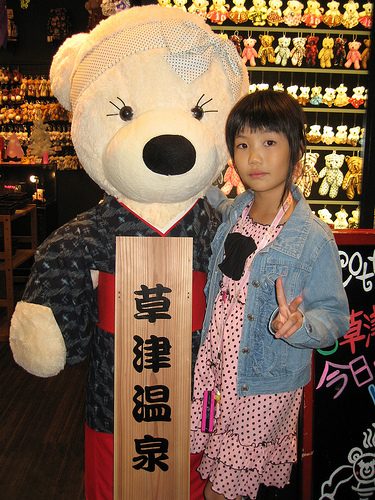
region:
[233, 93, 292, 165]
girl has brown hair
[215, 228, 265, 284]
girl has black bow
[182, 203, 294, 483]
girl has pink dress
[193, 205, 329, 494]
black dots on dress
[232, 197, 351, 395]
girl has blue jacket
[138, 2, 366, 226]
toy bears behind girl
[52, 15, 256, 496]
large bear next to girl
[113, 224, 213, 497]
black and brown sign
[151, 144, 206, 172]
bear has black nose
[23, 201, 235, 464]
black and grey shirt on bear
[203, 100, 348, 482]
a little girl that is posing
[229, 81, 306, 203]
the head of a little girl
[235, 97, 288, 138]
the bangs of a little girl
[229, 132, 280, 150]
the eyes of a little girl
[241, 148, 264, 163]
the nose of a little girl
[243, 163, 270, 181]
the mouth of a little girl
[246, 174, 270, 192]
the chin of a little girl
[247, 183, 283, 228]
the neck of a little girl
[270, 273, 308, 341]
the hand of a little girl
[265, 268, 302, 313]
the fingers of a little girl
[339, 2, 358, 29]
teddy bear on shelf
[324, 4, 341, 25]
teddy bear on shelf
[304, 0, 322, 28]
teddy bear on shelf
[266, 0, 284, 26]
teddy bear on shelf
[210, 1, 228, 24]
teddy bear on shelf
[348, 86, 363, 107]
teddy bear on shelf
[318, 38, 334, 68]
teddy bear on shelf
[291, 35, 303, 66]
teddy bear on shelf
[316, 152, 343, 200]
teddy bear on shelf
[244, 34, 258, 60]
teddy bear hung up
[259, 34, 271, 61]
teddy bear hung up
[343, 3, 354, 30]
teddy bear hung up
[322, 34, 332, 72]
teddy bear hung up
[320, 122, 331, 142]
teddy bear hung up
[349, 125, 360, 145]
teddy bear hung up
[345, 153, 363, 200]
teddy bear hung up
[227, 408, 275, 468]
black polka dots on dress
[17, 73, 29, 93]
teddy bear hung up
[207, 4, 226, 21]
teddy bear hung up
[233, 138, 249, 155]
the eye of a woman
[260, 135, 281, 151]
the eye of a woman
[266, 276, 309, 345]
a hand making the peace sign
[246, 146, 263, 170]
a nose of a woman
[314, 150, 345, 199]
a teddy bear hanging in a shelf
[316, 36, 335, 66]
a teddy bear hanging in a shelf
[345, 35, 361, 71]
a teddy bear hanging in a shelf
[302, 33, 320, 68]
a teddy bear hanging in a shelf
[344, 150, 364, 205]
a teddy bear hanging in a shelf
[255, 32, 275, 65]
a teddy bear hanging in a shelf